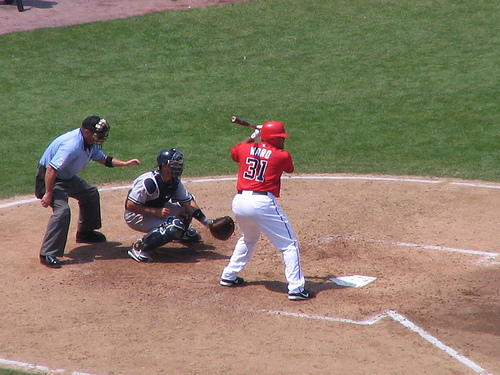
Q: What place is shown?
A: It is a field.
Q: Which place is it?
A: It is a field.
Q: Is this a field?
A: Yes, it is a field.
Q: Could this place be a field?
A: Yes, it is a field.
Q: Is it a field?
A: Yes, it is a field.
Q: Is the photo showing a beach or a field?
A: It is showing a field.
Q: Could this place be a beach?
A: No, it is a field.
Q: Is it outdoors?
A: Yes, it is outdoors.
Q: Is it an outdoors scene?
A: Yes, it is outdoors.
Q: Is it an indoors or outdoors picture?
A: It is outdoors.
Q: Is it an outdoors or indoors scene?
A: It is outdoors.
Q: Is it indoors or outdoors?
A: It is outdoors.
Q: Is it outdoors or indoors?
A: It is outdoors.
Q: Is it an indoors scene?
A: No, it is outdoors.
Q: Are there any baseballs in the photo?
A: Yes, there is a baseball.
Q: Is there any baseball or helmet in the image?
A: Yes, there is a baseball.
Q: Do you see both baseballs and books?
A: No, there is a baseball but no books.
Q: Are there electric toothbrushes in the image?
A: No, there are no electric toothbrushes.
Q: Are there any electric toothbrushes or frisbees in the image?
A: No, there are no electric toothbrushes or frisbees.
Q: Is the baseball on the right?
A: Yes, the baseball is on the right of the image.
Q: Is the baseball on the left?
A: No, the baseball is on the right of the image.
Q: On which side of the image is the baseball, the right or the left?
A: The baseball is on the right of the image.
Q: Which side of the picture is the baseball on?
A: The baseball is on the right of the image.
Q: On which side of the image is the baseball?
A: The baseball is on the right of the image.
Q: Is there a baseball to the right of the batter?
A: Yes, there is a baseball to the right of the batter.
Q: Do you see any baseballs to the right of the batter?
A: Yes, there is a baseball to the right of the batter.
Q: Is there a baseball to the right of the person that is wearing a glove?
A: Yes, there is a baseball to the right of the batter.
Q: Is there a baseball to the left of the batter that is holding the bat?
A: No, the baseball is to the right of the batter.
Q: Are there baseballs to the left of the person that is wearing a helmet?
A: No, the baseball is to the right of the batter.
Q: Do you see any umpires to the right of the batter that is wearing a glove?
A: No, there is a baseball to the right of the batter.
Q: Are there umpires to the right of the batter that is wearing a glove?
A: No, there is a baseball to the right of the batter.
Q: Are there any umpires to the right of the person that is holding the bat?
A: No, there is a baseball to the right of the batter.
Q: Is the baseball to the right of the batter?
A: Yes, the baseball is to the right of the batter.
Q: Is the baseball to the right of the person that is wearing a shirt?
A: Yes, the baseball is to the right of the batter.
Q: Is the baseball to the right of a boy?
A: No, the baseball is to the right of the batter.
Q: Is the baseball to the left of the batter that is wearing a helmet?
A: No, the baseball is to the right of the batter.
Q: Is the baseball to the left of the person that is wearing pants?
A: No, the baseball is to the right of the batter.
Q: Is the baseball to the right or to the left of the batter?
A: The baseball is to the right of the batter.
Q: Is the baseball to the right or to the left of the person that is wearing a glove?
A: The baseball is to the right of the batter.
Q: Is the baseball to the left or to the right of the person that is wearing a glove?
A: The baseball is to the right of the batter.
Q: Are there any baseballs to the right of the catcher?
A: Yes, there is a baseball to the right of the catcher.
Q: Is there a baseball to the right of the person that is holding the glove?
A: Yes, there is a baseball to the right of the catcher.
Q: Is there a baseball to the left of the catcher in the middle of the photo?
A: No, the baseball is to the right of the catcher.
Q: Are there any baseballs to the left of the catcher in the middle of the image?
A: No, the baseball is to the right of the catcher.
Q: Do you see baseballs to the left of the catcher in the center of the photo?
A: No, the baseball is to the right of the catcher.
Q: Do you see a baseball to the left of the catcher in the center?
A: No, the baseball is to the right of the catcher.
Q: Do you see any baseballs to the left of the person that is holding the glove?
A: No, the baseball is to the right of the catcher.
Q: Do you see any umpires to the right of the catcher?
A: No, there is a baseball to the right of the catcher.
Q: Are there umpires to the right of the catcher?
A: No, there is a baseball to the right of the catcher.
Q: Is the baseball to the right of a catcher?
A: Yes, the baseball is to the right of a catcher.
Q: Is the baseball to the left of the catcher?
A: No, the baseball is to the right of the catcher.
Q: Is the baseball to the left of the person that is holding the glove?
A: No, the baseball is to the right of the catcher.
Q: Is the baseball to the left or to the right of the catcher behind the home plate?
A: The baseball is to the right of the catcher.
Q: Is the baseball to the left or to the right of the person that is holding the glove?
A: The baseball is to the right of the catcher.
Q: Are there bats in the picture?
A: Yes, there is a bat.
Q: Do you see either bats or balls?
A: Yes, there is a bat.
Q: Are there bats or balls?
A: Yes, there is a bat.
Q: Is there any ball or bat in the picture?
A: Yes, there is a bat.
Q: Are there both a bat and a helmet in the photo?
A: Yes, there are both a bat and a helmet.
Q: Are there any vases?
A: No, there are no vases.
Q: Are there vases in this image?
A: No, there are no vases.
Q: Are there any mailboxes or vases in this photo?
A: No, there are no vases or mailboxes.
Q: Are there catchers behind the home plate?
A: Yes, there is a catcher behind the home plate.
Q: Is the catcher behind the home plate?
A: Yes, the catcher is behind the home plate.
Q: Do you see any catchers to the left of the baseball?
A: Yes, there is a catcher to the left of the baseball.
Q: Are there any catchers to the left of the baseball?
A: Yes, there is a catcher to the left of the baseball.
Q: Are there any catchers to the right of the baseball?
A: No, the catcher is to the left of the baseball.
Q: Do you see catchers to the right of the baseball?
A: No, the catcher is to the left of the baseball.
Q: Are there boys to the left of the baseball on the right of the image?
A: No, there is a catcher to the left of the baseball.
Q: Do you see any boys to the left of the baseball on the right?
A: No, there is a catcher to the left of the baseball.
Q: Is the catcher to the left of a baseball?
A: Yes, the catcher is to the left of a baseball.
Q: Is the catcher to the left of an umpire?
A: No, the catcher is to the left of a baseball.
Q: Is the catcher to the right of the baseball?
A: No, the catcher is to the left of the baseball.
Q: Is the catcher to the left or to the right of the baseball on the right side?
A: The catcher is to the left of the baseball.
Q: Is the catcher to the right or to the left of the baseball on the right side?
A: The catcher is to the left of the baseball.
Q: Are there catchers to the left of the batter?
A: Yes, there is a catcher to the left of the batter.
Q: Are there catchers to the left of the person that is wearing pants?
A: Yes, there is a catcher to the left of the batter.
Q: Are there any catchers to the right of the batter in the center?
A: No, the catcher is to the left of the batter.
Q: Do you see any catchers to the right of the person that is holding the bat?
A: No, the catcher is to the left of the batter.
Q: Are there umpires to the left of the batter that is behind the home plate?
A: No, there is a catcher to the left of the batter.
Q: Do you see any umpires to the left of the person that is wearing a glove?
A: No, there is a catcher to the left of the batter.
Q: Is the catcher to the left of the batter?
A: Yes, the catcher is to the left of the batter.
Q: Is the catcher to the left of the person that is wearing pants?
A: Yes, the catcher is to the left of the batter.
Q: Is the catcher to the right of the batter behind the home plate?
A: No, the catcher is to the left of the batter.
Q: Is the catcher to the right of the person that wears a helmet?
A: No, the catcher is to the left of the batter.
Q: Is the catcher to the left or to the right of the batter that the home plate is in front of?
A: The catcher is to the left of the batter.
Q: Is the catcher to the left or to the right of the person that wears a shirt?
A: The catcher is to the left of the batter.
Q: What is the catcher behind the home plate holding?
A: The catcher is holding the glove.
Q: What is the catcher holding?
A: The catcher is holding the glove.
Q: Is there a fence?
A: No, there are no fences.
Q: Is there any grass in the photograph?
A: Yes, there is grass.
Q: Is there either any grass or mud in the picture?
A: Yes, there is grass.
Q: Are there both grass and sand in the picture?
A: No, there is grass but no sand.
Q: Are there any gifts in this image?
A: No, there are no gifts.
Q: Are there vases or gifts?
A: No, there are no gifts or vases.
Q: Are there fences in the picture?
A: No, there are no fences.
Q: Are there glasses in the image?
A: No, there are no glasses.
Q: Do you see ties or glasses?
A: No, there are no glasses or ties.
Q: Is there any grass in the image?
A: Yes, there is grass.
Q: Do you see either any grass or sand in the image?
A: Yes, there is grass.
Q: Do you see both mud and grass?
A: No, there is grass but no mud.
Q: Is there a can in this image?
A: No, there are no cans.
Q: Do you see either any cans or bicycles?
A: No, there are no cans or bicycles.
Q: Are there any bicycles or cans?
A: No, there are no cans or bicycles.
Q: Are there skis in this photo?
A: No, there are no skis.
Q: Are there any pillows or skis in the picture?
A: No, there are no skis or pillows.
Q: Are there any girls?
A: No, there are no girls.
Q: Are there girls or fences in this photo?
A: No, there are no girls or fences.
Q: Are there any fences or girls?
A: No, there are no girls or fences.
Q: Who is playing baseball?
A: The batter is playing baseball.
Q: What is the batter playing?
A: The batter is playing baseball.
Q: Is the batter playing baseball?
A: Yes, the batter is playing baseball.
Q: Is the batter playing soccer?
A: No, the batter is playing baseball.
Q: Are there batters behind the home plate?
A: Yes, there is a batter behind the home plate.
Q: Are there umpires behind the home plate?
A: No, there is a batter behind the home plate.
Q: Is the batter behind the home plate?
A: Yes, the batter is behind the home plate.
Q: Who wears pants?
A: The batter wears pants.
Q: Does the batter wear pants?
A: Yes, the batter wears pants.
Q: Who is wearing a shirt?
A: The batter is wearing a shirt.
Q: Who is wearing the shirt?
A: The batter is wearing a shirt.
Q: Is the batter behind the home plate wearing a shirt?
A: Yes, the batter is wearing a shirt.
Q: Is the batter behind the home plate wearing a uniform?
A: No, the batter is wearing a shirt.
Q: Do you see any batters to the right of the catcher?
A: Yes, there is a batter to the right of the catcher.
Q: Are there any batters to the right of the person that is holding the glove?
A: Yes, there is a batter to the right of the catcher.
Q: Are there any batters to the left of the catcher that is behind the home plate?
A: No, the batter is to the right of the catcher.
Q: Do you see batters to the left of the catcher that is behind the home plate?
A: No, the batter is to the right of the catcher.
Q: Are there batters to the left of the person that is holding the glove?
A: No, the batter is to the right of the catcher.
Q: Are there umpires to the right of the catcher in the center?
A: No, there is a batter to the right of the catcher.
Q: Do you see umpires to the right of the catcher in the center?
A: No, there is a batter to the right of the catcher.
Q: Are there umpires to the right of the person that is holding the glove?
A: No, there is a batter to the right of the catcher.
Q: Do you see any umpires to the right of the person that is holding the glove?
A: No, there is a batter to the right of the catcher.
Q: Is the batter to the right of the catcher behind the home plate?
A: Yes, the batter is to the right of the catcher.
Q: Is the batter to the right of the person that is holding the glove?
A: Yes, the batter is to the right of the catcher.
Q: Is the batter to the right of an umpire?
A: No, the batter is to the right of the catcher.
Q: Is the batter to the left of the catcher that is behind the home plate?
A: No, the batter is to the right of the catcher.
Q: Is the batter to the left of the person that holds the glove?
A: No, the batter is to the right of the catcher.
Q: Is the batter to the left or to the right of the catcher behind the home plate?
A: The batter is to the right of the catcher.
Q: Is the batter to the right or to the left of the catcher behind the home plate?
A: The batter is to the right of the catcher.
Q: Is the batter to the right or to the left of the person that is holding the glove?
A: The batter is to the right of the catcher.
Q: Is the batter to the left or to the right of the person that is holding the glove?
A: The batter is to the right of the catcher.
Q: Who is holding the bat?
A: The batter is holding the bat.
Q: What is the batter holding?
A: The batter is holding the bat.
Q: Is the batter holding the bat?
A: Yes, the batter is holding the bat.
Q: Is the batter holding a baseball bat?
A: No, the batter is holding the bat.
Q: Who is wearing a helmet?
A: The batter is wearing a helmet.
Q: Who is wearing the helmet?
A: The batter is wearing a helmet.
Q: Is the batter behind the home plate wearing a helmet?
A: Yes, the batter is wearing a helmet.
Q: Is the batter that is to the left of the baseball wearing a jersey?
A: No, the batter is wearing a helmet.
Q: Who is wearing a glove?
A: The batter is wearing a glove.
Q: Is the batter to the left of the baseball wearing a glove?
A: Yes, the batter is wearing a glove.